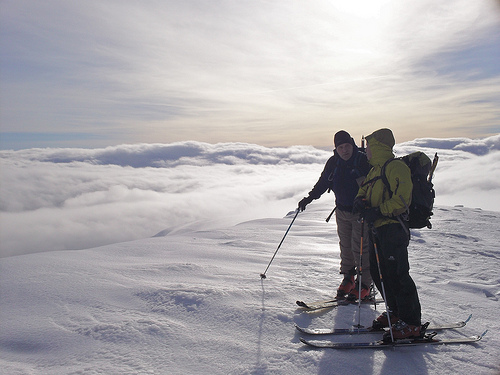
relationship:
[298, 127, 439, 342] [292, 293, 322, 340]
people people on skis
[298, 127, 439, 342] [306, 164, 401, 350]
people are two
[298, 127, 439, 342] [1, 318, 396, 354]
people skiers stand at edge of a cliff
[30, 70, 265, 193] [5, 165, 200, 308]
clouds are seen beyond cliff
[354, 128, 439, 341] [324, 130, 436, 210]
man in yellow jacket wearing a backpack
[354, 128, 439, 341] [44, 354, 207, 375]
man are standing on snowy ground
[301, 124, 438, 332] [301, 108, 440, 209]
talking two men are talking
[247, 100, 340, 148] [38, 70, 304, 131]
sun reflecting on snow and clouds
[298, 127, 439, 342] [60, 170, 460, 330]
people skiers at what looks like edge of world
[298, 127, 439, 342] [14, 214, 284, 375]
people two skiers are above cloud line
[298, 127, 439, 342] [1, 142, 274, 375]
people skiers are at edge of a dropoff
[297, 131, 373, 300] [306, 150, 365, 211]
man on right wearing a green coats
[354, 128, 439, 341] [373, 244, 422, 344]
man on left wearing light colored ski pants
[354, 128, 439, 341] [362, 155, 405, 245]
man on right wearing h hood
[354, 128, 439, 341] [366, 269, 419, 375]
man on right wearing dark ski pants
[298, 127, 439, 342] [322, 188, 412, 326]
people skiers standing on snow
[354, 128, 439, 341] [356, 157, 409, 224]
man wearing yellow coat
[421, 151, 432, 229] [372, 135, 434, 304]
backpack skier wearing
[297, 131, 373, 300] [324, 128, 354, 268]
man wearing dark colored coat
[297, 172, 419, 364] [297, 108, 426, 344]
two sets of skis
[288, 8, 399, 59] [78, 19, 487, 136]
sun in clouds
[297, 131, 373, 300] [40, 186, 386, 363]
man on snow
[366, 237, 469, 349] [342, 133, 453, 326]
pants on skier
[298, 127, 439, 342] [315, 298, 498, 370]
people on skis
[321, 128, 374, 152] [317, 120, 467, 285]
hats on people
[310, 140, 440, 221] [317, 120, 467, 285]
coats on people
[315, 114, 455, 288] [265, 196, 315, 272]
people with poles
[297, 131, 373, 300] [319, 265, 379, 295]
man with boots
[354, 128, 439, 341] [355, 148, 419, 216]
man with coat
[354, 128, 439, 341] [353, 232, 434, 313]
man with pants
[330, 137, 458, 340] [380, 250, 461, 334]
man with pants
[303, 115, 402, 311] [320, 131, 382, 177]
man with hat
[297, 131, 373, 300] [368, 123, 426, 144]
man with hat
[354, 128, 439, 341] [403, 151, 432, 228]
man with backpack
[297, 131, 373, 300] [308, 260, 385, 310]
man with sneakers